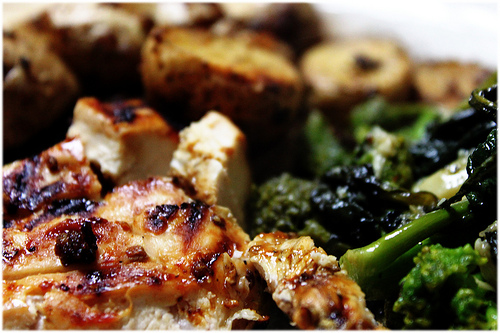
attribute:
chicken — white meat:
[77, 87, 252, 204]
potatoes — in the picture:
[6, 7, 451, 146]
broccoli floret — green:
[387, 237, 499, 332]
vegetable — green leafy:
[344, 132, 498, 284]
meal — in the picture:
[3, 0, 498, 332]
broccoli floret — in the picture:
[258, 171, 330, 241]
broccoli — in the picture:
[392, 232, 499, 315]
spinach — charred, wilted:
[280, 102, 498, 327]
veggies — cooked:
[250, 84, 497, 330]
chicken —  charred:
[55, 222, 95, 272]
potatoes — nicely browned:
[5, 3, 487, 150]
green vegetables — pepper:
[257, 97, 498, 332]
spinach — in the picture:
[268, 140, 409, 252]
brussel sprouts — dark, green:
[231, 167, 403, 275]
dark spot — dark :
[53, 221, 98, 267]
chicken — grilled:
[1, 99, 387, 332]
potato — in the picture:
[309, 36, 434, 104]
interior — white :
[107, 298, 196, 327]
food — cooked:
[74, 244, 271, 333]